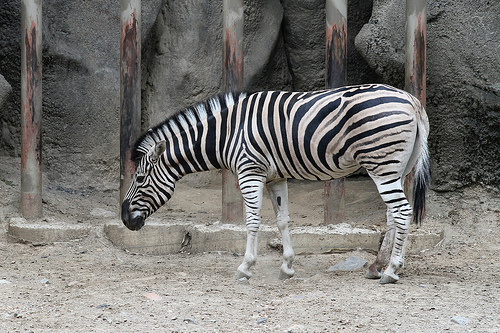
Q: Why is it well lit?
A: It's daytime.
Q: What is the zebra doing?
A: Standing.